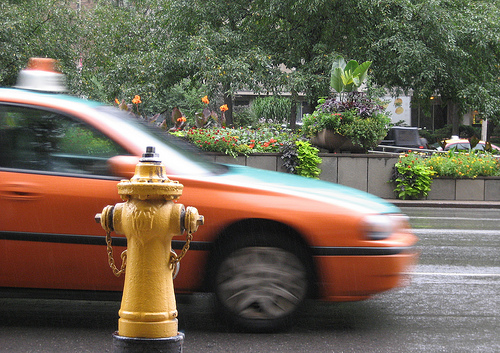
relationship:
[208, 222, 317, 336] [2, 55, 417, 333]
wheel belongs to car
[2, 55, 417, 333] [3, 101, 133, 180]
car has window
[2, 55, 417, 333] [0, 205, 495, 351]
car on street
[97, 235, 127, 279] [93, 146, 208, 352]
chain on fire hydrant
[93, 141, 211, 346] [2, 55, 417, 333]
fire hydrant in front of car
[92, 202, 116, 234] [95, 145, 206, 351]
faucet of hydrant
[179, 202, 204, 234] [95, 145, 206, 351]
faucet of hydrant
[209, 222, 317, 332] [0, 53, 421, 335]
wheel of taxi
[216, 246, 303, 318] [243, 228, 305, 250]
grill of tire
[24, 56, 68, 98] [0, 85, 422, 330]
sign on a taxi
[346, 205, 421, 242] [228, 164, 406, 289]
streetlight on a taxi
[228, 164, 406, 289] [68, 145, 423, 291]
taxi on a taxi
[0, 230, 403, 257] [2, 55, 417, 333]
bumper of a car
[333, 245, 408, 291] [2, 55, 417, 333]
bumper on car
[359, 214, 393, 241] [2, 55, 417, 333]
streetlight on car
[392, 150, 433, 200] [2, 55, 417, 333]
plant behind car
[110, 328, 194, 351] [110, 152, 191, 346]
base of a hydrant